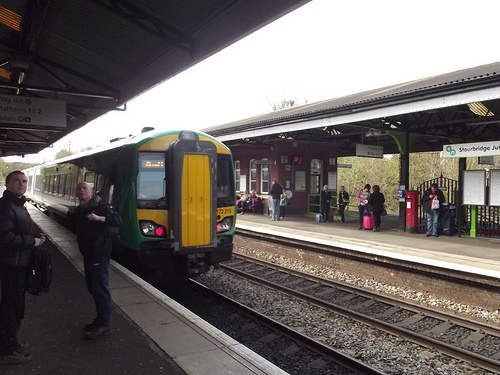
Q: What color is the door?
A: Yellow.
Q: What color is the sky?
A: White.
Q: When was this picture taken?
A: Day time.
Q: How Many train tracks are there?
A: 2.